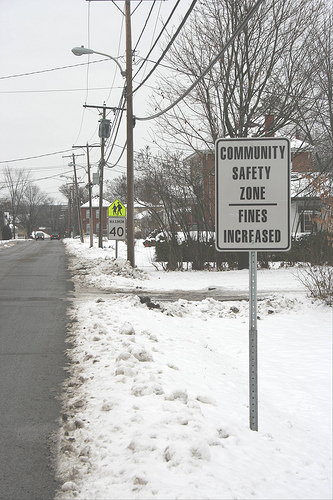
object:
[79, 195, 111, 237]
house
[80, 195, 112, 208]
roof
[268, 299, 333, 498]
snow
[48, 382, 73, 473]
snow patch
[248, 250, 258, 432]
pole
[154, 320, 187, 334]
snow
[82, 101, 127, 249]
telephone pole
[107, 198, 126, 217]
sign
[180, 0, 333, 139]
branches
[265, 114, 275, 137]
chimney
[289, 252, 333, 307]
circle planting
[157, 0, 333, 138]
tree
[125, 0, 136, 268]
pole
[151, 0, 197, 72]
power lines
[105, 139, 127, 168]
power lines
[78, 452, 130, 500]
snow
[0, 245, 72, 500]
road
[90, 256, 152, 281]
snow pile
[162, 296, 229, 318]
snow pile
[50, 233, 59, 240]
cars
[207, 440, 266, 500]
snow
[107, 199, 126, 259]
street sign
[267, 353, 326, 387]
patch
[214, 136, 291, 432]
post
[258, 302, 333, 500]
snow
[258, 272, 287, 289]
snow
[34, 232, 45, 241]
car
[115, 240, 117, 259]
pole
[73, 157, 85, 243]
pole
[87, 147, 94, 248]
pole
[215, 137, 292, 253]
sign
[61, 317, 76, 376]
snow patch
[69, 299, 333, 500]
ground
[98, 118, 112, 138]
transformer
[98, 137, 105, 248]
pole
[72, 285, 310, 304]
driveway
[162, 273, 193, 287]
snow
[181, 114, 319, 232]
house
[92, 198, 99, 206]
snow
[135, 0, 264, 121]
wires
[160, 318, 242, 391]
snow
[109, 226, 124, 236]
40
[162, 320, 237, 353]
patch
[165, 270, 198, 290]
patch